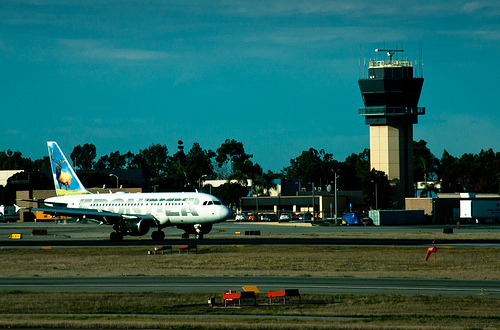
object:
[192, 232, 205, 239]
landing gear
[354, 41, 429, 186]
traffic tower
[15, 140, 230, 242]
jetliner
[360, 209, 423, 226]
storage building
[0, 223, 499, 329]
airport